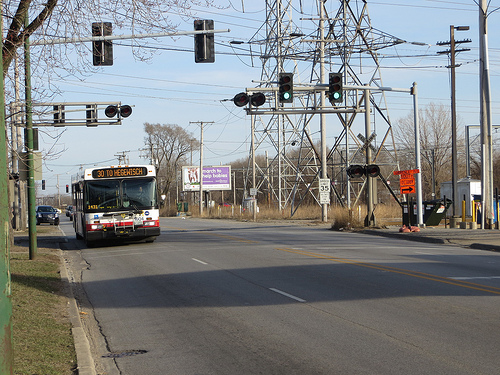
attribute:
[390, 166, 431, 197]
sign — orange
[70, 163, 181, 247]
bus — here, big, white, visable, moving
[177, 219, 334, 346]
road — black, paved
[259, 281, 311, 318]
line — white, hanging, green, black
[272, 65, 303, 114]
light — close, here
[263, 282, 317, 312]
lines — white, dashed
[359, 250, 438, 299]
line — yellow, double